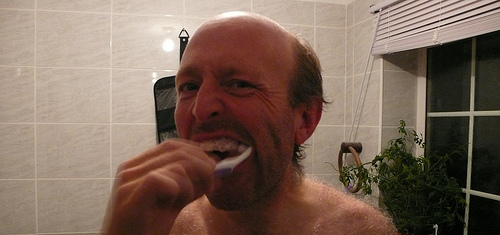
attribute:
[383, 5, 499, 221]
window — mini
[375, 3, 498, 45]
mini-blinds — white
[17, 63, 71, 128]
grout — white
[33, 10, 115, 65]
tiles — white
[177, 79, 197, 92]
eye — intense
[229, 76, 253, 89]
eye — intense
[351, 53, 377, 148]
rod — white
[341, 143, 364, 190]
towel rack — round, brown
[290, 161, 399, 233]
shoulder — hairy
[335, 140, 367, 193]
towel ring — brown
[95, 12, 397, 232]
man — middle aged